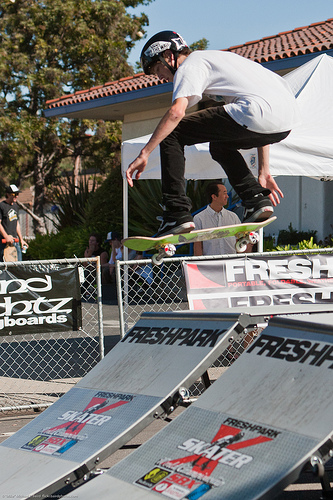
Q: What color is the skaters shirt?
A: White.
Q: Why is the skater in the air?
A: He is jumping.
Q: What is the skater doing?
A: Performing a skateboard trick.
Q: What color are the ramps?
A: Silver.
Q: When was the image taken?
A: During the day.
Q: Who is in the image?
A: Five people at a skatepark.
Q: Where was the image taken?
A: Skateboard competition.